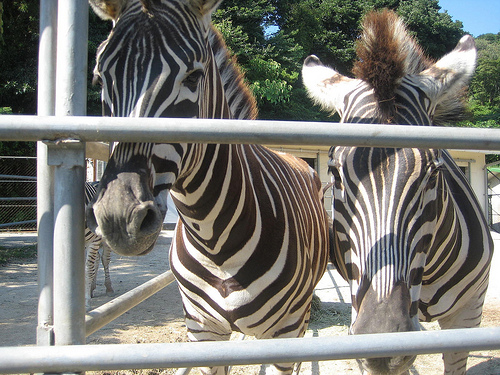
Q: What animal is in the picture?
A: Zebra.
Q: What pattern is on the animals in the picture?
A: Stripes.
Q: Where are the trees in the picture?
A: Behind the animals.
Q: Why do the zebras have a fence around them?
A: Keep them in one place.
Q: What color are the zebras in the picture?
A: White and black.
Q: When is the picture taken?
A: Daytime.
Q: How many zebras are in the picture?
A: Three.